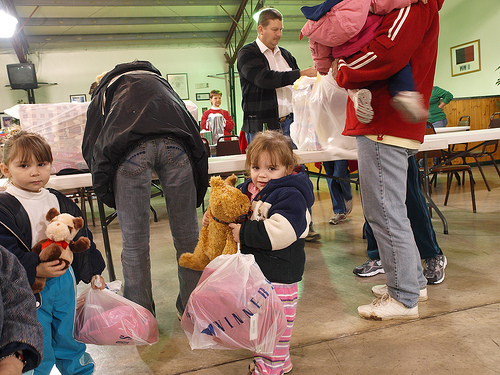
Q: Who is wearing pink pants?
A: Girl.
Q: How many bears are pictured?
A: 2.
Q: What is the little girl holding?
A: Bear.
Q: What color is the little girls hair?
A: Brown.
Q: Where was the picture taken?
A: Building.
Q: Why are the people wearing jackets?
A: Cold.